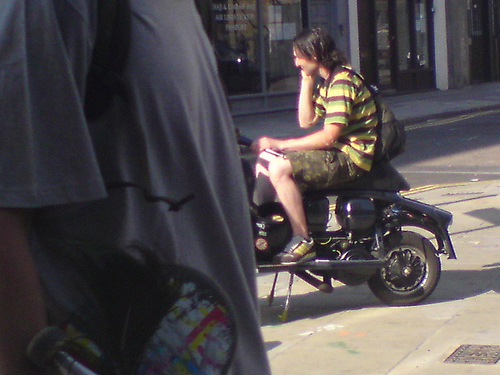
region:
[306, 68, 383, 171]
the man is wearing a short sleeve shirt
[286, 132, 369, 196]
the man is wearing shorts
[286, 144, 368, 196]
the shorts have a camouflage pattern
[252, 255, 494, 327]
a shadow is on the pavement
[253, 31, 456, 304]
the man is sitting on a motocycle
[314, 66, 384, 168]
the shirt is multi colored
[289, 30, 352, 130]
the man is talking on a cell phone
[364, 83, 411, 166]
the man is wearing a backpack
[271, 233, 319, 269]
the man is wearing athletic shoes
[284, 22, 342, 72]
the man's hair is long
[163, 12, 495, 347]
a man on a bike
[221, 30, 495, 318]
a man on a motorcycle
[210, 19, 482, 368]
a man on a prompted up bike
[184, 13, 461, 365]
a man on a prompted up motorcycle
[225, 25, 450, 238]
a man with long hair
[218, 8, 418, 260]
a man on the phone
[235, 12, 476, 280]
a man wearing a shirt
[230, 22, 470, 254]
a man wearing a striped shirt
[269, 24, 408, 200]
a man wearing a red purple yellow shirt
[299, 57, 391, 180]
red purple yellow stripes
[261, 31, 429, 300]
A man sitting on a motor bike.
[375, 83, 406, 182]
The man has a backpack on his back.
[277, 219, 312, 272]
The man is wearing tennis shoes.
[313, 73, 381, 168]
The man shirt is striped.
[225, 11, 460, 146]
The man is standing in front of the building.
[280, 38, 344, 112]
The man is talking on a cellphone.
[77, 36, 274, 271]
The person is wearing a gray shirt.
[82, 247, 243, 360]
The man is carrying a bag in his hand.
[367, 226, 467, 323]
The tire on the motorbike.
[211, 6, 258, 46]
The glass window has writing on it.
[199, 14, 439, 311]
man sitting on a motorcycle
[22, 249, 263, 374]
the underside of a skateboard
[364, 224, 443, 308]
motorcycle wheel with a black tire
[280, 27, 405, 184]
man wearing a striped shirt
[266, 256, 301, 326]
pair of kickstands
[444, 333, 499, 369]
metal grate on the road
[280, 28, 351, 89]
man with medium length hair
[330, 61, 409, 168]
black backpack hanging on shoulders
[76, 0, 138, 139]
black strap of a backpack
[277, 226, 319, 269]
white black and yellow sneakers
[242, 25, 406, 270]
white male on motorcycle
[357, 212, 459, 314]
small back cycle tire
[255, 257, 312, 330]
silver metal kick stant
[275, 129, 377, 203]
green camo cargo shorts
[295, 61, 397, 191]
brown yellow green striped shirt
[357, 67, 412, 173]
low slung green backpack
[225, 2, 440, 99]
tall glass store windows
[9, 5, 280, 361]
men's gray tee shirt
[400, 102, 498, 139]
long cement sidewalk curb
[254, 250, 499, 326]
cycle shadow cast on ground